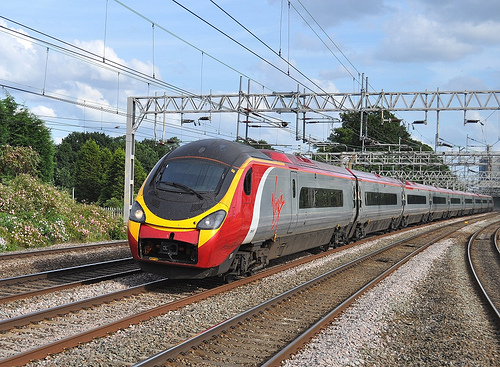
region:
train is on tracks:
[128, 139, 497, 319]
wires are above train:
[24, 16, 358, 127]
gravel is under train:
[127, 275, 209, 309]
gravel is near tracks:
[397, 273, 457, 348]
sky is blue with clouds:
[70, 22, 453, 79]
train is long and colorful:
[130, 137, 497, 273]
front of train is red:
[137, 149, 270, 269]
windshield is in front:
[157, 152, 224, 199]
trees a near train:
[5, 106, 141, 217]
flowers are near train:
[8, 178, 102, 240]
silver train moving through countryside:
[93, 90, 493, 263]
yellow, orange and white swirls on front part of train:
[111, 117, 276, 273]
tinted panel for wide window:
[132, 147, 232, 202]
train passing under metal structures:
[105, 80, 490, 211]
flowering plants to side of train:
[0, 147, 112, 248]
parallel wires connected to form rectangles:
[20, 25, 350, 102]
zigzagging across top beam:
[125, 77, 490, 123]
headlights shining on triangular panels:
[126, 195, 236, 230]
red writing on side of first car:
[260, 170, 290, 241]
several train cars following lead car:
[122, 142, 497, 280]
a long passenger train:
[123, 136, 498, 282]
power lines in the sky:
[3, 2, 404, 149]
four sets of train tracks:
[1, 272, 499, 365]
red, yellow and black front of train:
[126, 136, 268, 277]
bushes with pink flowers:
[0, 171, 129, 243]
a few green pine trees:
[73, 138, 146, 208]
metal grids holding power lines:
[122, 86, 499, 190]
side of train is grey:
[254, 160, 496, 259]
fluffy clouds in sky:
[0, 18, 181, 141]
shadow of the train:
[29, 247, 146, 289]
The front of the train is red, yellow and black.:
[106, 122, 261, 281]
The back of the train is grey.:
[242, 125, 499, 287]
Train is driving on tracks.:
[48, 245, 274, 365]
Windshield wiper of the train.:
[156, 166, 198, 200]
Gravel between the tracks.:
[316, 319, 488, 363]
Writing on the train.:
[254, 174, 306, 249]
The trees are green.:
[16, 113, 106, 178]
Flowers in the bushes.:
[9, 172, 54, 237]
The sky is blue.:
[70, 0, 230, 55]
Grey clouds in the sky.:
[318, 1, 493, 73]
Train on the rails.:
[92, 107, 453, 336]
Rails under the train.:
[297, 218, 408, 365]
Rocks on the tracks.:
[377, 250, 466, 340]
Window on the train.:
[103, 141, 259, 227]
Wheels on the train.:
[248, 210, 275, 298]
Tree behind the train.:
[318, 75, 440, 197]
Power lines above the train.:
[80, 38, 252, 145]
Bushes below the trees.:
[30, 101, 128, 271]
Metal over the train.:
[178, 83, 460, 158]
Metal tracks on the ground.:
[235, 266, 303, 361]